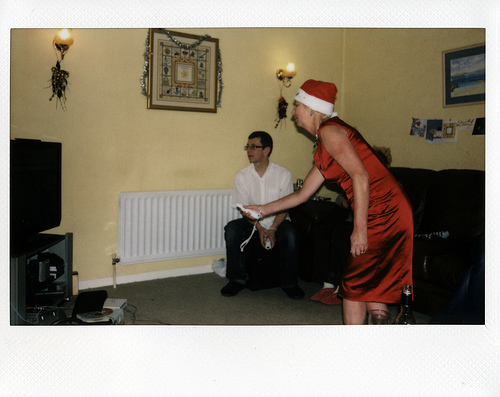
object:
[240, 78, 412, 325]
woman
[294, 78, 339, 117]
hat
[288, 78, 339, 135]
head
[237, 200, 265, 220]
hand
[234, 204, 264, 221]
remote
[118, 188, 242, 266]
radiator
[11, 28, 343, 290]
wall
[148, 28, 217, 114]
picture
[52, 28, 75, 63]
lamp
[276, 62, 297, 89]
lamp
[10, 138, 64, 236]
tv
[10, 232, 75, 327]
stand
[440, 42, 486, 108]
picture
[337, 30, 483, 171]
wall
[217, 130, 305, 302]
man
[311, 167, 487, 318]
couch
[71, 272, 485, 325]
carpet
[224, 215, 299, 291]
jeans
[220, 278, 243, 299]
shoes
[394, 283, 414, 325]
bottle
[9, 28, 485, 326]
background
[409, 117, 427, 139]
photo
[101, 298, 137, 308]
wii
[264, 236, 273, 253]
controller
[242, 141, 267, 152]
glasses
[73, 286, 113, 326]
case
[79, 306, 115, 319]
discs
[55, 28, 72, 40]
light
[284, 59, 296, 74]
light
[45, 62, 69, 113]
quilt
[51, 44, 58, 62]
string